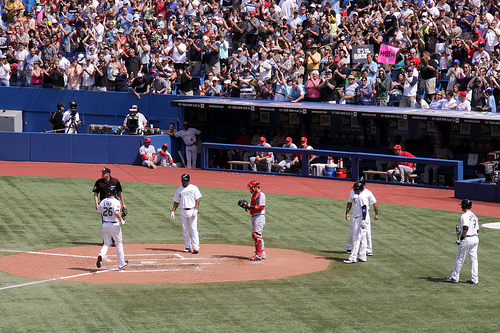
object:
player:
[169, 172, 203, 255]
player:
[236, 178, 268, 262]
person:
[169, 173, 203, 255]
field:
[0, 160, 500, 333]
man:
[61, 101, 81, 134]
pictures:
[69, 111, 78, 119]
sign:
[377, 43, 401, 65]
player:
[94, 182, 131, 271]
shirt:
[92, 175, 123, 202]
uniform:
[172, 183, 203, 251]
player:
[341, 180, 372, 264]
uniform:
[348, 195, 369, 263]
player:
[443, 198, 481, 286]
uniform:
[451, 210, 481, 284]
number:
[103, 206, 113, 216]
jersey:
[96, 197, 121, 223]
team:
[137, 120, 455, 185]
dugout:
[168, 96, 500, 202]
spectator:
[0, 2, 500, 113]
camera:
[127, 104, 140, 132]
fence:
[0, 131, 174, 165]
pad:
[251, 231, 265, 257]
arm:
[248, 193, 266, 211]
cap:
[99, 167, 110, 174]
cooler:
[324, 164, 338, 177]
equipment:
[237, 179, 267, 261]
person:
[123, 104, 149, 136]